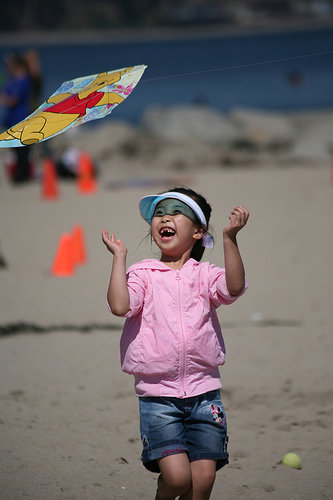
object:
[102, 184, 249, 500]
girl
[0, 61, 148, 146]
kite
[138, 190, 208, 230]
visor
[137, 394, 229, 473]
shorts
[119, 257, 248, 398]
jacket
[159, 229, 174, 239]
teeth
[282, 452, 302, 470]
ball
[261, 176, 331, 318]
sand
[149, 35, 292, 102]
water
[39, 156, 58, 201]
cone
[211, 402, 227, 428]
character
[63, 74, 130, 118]
character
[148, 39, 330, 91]
string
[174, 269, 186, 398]
zipper